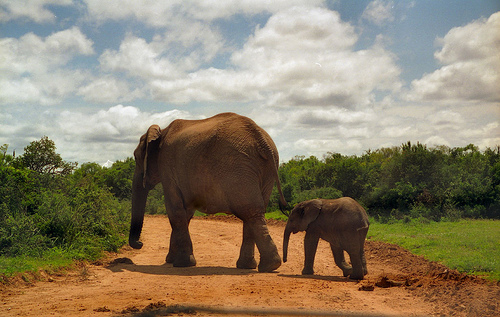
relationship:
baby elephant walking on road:
[276, 181, 382, 281] [1, 215, 497, 312]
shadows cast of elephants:
[102, 254, 377, 279] [124, 115, 281, 273]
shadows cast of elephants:
[102, 254, 377, 279] [277, 195, 374, 281]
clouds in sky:
[2, 0, 497, 172] [1, 1, 499, 175]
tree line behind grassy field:
[88, 137, 498, 225] [376, 219, 498, 285]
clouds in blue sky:
[2, 0, 497, 172] [0, 2, 500, 112]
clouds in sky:
[2, 0, 497, 172] [1, 2, 496, 145]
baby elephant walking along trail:
[276, 196, 374, 281] [0, 217, 498, 314]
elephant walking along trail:
[127, 111, 292, 273] [0, 217, 498, 314]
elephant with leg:
[127, 111, 292, 273] [158, 188, 196, 268]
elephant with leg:
[127, 111, 292, 273] [236, 218, 256, 268]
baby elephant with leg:
[276, 196, 374, 281] [241, 212, 280, 274]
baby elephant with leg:
[276, 196, 374, 281] [300, 229, 318, 275]